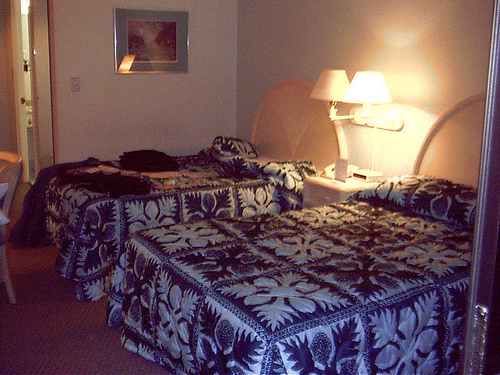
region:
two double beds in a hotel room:
[39, 40, 458, 360]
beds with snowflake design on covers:
[190, 237, 332, 337]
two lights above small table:
[318, 67, 405, 142]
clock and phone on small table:
[316, 162, 381, 189]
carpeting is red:
[33, 298, 87, 353]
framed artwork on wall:
[90, 4, 197, 76]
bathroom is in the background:
[9, 14, 74, 169]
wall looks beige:
[85, 93, 175, 137]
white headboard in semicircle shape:
[245, 70, 359, 178]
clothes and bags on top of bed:
[32, 142, 189, 209]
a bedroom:
[16, 5, 488, 373]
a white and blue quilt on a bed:
[127, 215, 497, 370]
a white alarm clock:
[355, 164, 383, 186]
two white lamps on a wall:
[307, 62, 418, 137]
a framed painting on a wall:
[101, 7, 206, 82]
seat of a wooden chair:
[0, 145, 30, 240]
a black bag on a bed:
[116, 142, 184, 172]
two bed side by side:
[40, 81, 487, 373]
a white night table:
[307, 170, 374, 207]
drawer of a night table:
[301, 179, 345, 205]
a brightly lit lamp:
[340, 61, 391, 127]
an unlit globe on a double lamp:
[310, 50, 351, 112]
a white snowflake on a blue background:
[217, 256, 360, 346]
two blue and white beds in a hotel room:
[48, 120, 478, 348]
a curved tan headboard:
[239, 78, 333, 153]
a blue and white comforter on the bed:
[237, 213, 399, 318]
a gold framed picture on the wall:
[100, 4, 195, 81]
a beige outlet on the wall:
[63, 72, 85, 97]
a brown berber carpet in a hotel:
[28, 306, 96, 368]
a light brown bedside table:
[300, 167, 363, 207]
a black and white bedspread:
[108, 167, 474, 371]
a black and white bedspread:
[31, 141, 307, 292]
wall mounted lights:
[309, 68, 406, 133]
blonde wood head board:
[243, 77, 347, 175]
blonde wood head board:
[403, 94, 493, 184]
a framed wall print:
[111, 6, 191, 81]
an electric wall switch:
[65, 75, 85, 95]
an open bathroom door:
[10, 0, 34, 180]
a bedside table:
[298, 167, 373, 203]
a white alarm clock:
[351, 166, 383, 183]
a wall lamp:
[310, 62, 404, 134]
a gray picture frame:
[107, 7, 194, 78]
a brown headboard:
[249, 77, 349, 172]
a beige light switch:
[66, 73, 81, 93]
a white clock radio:
[352, 165, 378, 182]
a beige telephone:
[312, 160, 357, 181]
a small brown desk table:
[297, 171, 368, 204]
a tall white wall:
[51, 0, 241, 158]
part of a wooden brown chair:
[0, 150, 26, 306]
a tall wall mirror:
[28, 0, 55, 184]